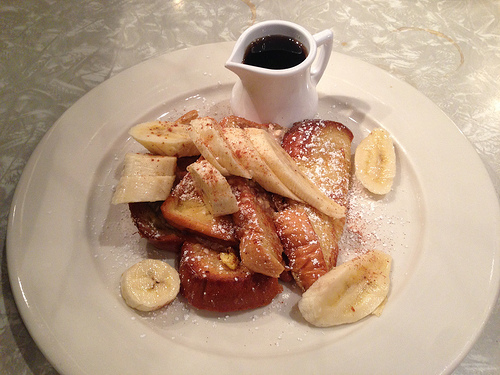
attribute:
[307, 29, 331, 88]
handle — white, ceramic, pitcher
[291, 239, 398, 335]
banana — part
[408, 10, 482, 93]
table top — gray, patterned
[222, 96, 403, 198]
banana — cut on bias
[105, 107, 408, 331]
breakfast — dish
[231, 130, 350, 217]
banana — piece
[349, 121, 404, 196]
banana — piece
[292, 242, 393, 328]
banana — piece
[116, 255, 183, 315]
banana — piece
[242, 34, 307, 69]
syrup — brown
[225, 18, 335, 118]
pitcher — ceramic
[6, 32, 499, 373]
plate — round, white, part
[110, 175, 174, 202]
banana — piece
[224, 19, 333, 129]
cup — syrup, brown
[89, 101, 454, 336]
banana — piece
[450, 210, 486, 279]
plate — part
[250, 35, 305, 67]
coffee — cup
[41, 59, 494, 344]
plate — light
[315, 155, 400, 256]
sugar — powered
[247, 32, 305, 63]
syrup — brown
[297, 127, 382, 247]
sugar — powdered 